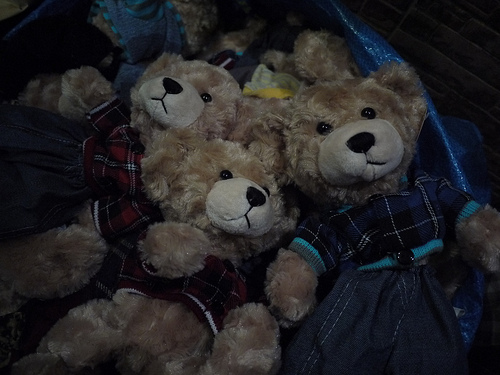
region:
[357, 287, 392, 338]
part of a cloth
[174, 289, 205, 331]
edge of a sweater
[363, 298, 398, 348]
part of a cloth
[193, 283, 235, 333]
part of a button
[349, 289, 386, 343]
part of a short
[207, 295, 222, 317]
part of a button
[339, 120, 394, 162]
nose of the teddy bear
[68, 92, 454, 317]
many different teddy bears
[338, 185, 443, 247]
lines on the shirt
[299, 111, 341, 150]
eye of the teddy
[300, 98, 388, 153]
two eyes of the teddy bear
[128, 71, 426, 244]
three heads of the teddy bears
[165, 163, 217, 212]
brown fur on teddy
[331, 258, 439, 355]
pants on the bear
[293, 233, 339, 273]
blue and gray sleeve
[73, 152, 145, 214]
red striped shirt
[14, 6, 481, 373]
a large bag of stuffed animals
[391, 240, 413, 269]
a shiny black button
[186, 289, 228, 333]
a white stripe on a sweater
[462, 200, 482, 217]
light blue trim on a sleeve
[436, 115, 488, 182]
the edge of blue plastic bag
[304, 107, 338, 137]
a round plastic eye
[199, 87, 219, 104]
a black shiny eye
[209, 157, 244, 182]
a black eye on head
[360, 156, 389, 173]
a stitched black mouth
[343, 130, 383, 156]
a black cloth nose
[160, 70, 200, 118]
Bear has black nose.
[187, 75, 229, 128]
Bear has black eye.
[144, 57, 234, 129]
Bear has brown head.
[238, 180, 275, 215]
Bear has black nose.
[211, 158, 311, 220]
Bear has dark eyes.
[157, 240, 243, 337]
Bear wearing red plaid shirt.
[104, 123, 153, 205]
Bear wearing red plaid shirt.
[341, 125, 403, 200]
Bear has black nose.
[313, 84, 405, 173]
Bear has dark eyes.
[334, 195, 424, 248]
Bear wearing blue plaid shirt.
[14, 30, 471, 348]
three teddy bears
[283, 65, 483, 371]
teddy bear on the right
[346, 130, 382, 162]
nose of the teddy bear on the right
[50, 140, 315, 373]
the teddy bear in the middle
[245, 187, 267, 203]
black nose of the teddy in the middle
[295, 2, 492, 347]
blue tarp the bears are lying on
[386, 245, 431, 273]
black button on teddy bear jersey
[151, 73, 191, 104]
nose of teddy bear on the right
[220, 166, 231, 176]
right eye of teddy bear in the middle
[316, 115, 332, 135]
right eye of teddy bear on the right